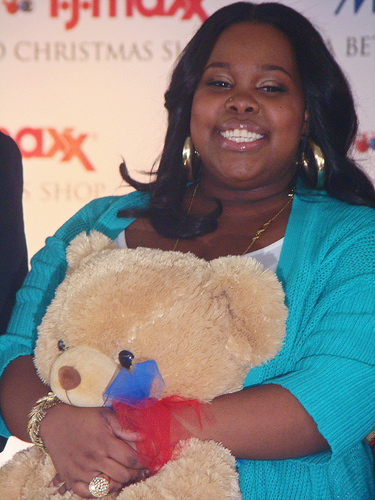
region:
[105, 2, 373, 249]
a woman with black hair.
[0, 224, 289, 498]
a large brown teddy bear.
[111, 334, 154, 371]
a brown teddy bear eye.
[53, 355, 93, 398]
a brown teddy bear nose.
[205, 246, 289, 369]
a brown teddy bear ear.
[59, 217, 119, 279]
a right teddy bear ear.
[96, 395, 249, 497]
a left teddy bear arm.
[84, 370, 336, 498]
the left arm of a woman.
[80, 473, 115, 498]
a ring on a finger.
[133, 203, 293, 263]
a golden necklace.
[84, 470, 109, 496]
Ring on right hand of young lady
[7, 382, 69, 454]
Young lady wearing bracelet on right wrist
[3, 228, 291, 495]
Stuffed teddy bear on young lady's lap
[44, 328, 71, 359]
Right eye of stuffed teddy bear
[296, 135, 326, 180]
Gold earrings in young lady's left ear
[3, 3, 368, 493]
Young lady holding stuffed teddy bear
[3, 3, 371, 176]
Advertisement on wall in back of young lady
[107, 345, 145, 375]
Left eye of stuffed teddy bear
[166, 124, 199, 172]
Earring in right ear of young lady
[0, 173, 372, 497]
Turquoise jacket young lady is wearing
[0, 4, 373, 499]
woman holds a teddy bear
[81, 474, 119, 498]
large ring on finger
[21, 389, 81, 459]
a gold bracelet on wrist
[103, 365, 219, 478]
blue and red ribbon on bear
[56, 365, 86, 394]
brown nose of bear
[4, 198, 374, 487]
woman wears blue sweater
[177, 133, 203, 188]
large gold hoop earrings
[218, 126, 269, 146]
several white teeth in smile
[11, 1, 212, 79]
Advertisment on the wall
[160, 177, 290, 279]
gold necklace on woman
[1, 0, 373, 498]
woman holding large tan teddy bear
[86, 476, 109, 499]
large round cocktail ring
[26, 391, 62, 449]
gold bracelet on wrist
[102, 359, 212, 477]
red and blue net tied around wrist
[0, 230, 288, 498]
large tan stuffed teddy bear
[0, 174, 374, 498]
turquoise blue knot sweater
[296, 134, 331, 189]
one large gold earring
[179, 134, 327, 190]
a pair of large gold hoop earrings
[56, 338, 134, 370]
bear's two black eyes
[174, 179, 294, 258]
gold neck chain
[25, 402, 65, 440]
women wearing a braclet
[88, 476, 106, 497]
a ring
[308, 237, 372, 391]
man wearing a light blue sweater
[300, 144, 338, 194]
a earring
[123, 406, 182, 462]
a red ribbon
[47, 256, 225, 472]
women is holding a teddy bear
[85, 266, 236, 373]
teddy bear is brown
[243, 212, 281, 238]
a necklace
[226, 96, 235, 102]
women is wearing a earring in her nose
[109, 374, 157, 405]
a blue ribbon